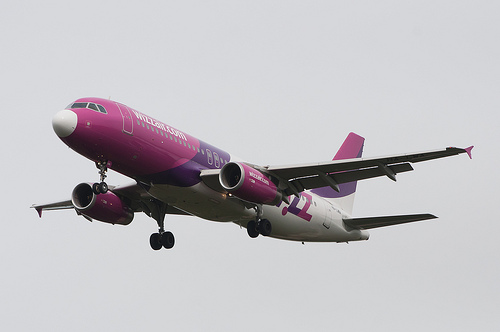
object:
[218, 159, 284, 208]
turbine engine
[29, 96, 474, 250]
plane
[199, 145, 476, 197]
wing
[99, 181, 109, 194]
wheel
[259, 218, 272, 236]
black wheel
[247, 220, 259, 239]
black wheel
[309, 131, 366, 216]
tail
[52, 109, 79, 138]
nose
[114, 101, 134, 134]
plane door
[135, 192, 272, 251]
landing gear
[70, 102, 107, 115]
windshield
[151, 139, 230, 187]
stripe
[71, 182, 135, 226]
engine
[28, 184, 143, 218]
wing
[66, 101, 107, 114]
cockpit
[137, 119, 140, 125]
window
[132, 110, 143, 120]
letter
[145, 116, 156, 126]
letter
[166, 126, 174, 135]
letter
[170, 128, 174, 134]
letter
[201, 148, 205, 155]
window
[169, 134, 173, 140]
window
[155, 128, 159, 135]
window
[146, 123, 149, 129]
window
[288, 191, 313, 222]
letter p